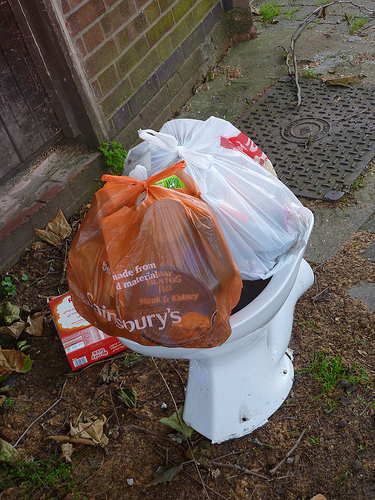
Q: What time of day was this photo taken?
A: Daytime.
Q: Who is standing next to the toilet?
A: No one.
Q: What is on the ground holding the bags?
A: Toilet.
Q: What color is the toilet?
A: White.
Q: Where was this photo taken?
A: UK.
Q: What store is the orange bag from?
A: Sainsbury's.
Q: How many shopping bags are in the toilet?
A: Two.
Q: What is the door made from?
A: Wood.